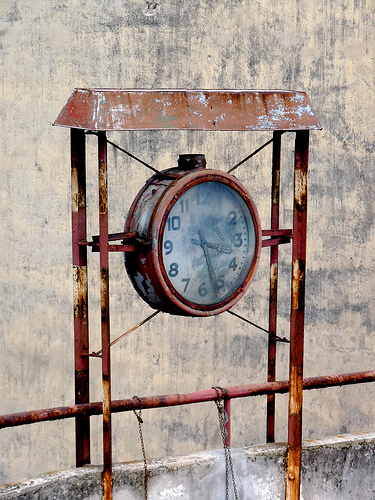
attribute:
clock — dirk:
[148, 159, 263, 318]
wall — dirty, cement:
[319, 42, 368, 352]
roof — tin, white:
[40, 67, 286, 134]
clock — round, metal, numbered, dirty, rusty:
[135, 154, 263, 317]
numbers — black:
[181, 275, 194, 292]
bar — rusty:
[68, 127, 90, 468]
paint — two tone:
[74, 265, 88, 321]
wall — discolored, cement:
[4, 430, 373, 498]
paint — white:
[87, 449, 373, 498]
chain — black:
[127, 392, 152, 498]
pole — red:
[1, 366, 369, 430]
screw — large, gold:
[285, 470, 297, 483]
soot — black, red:
[102, 396, 155, 409]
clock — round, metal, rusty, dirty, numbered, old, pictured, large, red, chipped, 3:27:
[118, 159, 263, 320]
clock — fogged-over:
[136, 167, 258, 314]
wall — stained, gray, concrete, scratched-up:
[1, 3, 373, 497]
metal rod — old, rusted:
[282, 129, 310, 498]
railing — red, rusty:
[0, 367, 372, 429]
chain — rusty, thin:
[204, 383, 238, 498]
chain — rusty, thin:
[126, 392, 149, 496]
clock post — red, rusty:
[53, 82, 323, 498]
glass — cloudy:
[164, 184, 252, 308]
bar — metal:
[115, 376, 297, 410]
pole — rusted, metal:
[96, 133, 127, 498]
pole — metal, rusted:
[70, 121, 95, 467]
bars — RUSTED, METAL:
[267, 257, 317, 371]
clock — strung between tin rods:
[119, 148, 273, 323]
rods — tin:
[108, 135, 153, 172]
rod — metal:
[111, 379, 285, 413]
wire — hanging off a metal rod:
[132, 417, 245, 498]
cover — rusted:
[127, 159, 262, 326]